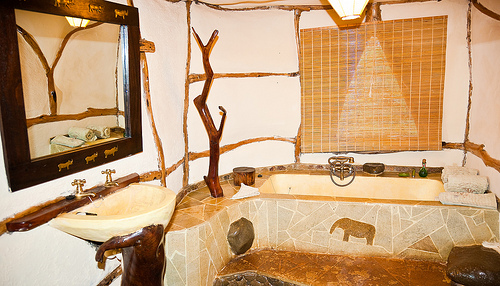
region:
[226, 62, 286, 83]
The crack in the wall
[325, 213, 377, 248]
An elephant design on the wall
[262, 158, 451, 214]
The bath tub in the bathroom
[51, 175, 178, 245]
The sink in the bathroom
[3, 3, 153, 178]
The mirror in the bathroom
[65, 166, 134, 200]
The faucet is the color gold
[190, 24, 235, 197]
The tree branch is the color brown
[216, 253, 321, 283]
A sitting area in the bathroom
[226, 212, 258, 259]
A rock on the side of the tub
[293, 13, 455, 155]
The window covering is the color brown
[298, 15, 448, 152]
the bamboo blinds hanging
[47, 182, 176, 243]
the bathroom sink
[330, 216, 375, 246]
the elephant on the tub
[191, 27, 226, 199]
the decorative branch on the tub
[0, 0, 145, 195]
the wooden framed mirror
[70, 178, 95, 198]
the bathroom sink fixture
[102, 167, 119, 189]
the bathroom sink fixture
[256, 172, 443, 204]
the bath tub near the bamboo blinds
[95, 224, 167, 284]
the dark wood under the sink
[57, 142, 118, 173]
the animals on the bottom of the mirror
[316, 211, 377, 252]
THIS IS AN ELEPHANT TILE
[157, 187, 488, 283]
THE BATHTUB IS SURROUNDED WITH DECORATIVE TILE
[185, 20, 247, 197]
THIS IS A DECORATIVE STICK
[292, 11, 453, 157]
THIS IS A BAMBOO SHADE FOR THE WINDOW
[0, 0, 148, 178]
THIS IS A SQUARE MIRROR WITH A WOODEN FRAME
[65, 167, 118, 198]
THIS IS THE FAUCETS TO THE SINK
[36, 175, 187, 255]
THIS IS THE SINK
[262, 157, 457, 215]
THIS IS THE TUB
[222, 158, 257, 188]
THIS IS A WOODEN BOX ON THE EDGE OF THE TUB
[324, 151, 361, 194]
THIS IS THE FAUCET TO THE TUB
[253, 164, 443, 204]
this is a sink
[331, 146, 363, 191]
this is a tap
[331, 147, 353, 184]
the tap is metallic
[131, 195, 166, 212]
the sink is white in color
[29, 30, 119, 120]
this is a picture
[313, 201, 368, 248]
this is a elephant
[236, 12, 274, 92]
this is the wall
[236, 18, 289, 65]
the wall is white in color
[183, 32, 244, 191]
this is a wood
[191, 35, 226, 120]
the wood is brown in color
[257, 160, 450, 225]
a rock timmed bathtub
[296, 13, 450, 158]
a wicker window covering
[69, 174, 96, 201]
a faucet of a bathroom sink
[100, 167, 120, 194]
a faucet of a bathroom sink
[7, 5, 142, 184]
a mirror on a wall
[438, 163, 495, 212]
some towels at the side of a bathtub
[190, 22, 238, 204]
a tree branch decoration in a bathroom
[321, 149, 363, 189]
the faucet in a bathtub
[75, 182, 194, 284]
a bathroom sink on a wood log pedestal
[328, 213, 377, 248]
an elephant decoration on the side of a bathtub